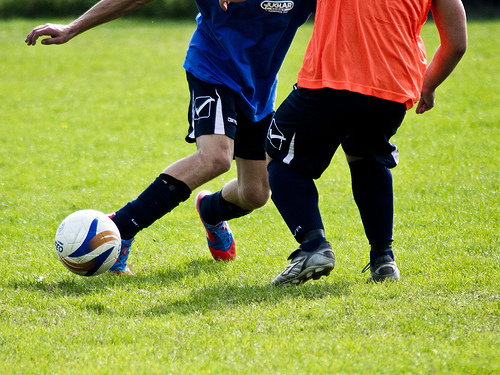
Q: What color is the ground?
A: Green.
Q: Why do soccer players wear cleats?
A: For traction.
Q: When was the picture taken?
A: Daytime.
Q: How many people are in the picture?
A: Two.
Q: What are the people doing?
A: Playing soccer.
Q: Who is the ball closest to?
A: The man with the blue shirt.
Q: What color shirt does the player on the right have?
A: Orange.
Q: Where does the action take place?
A: On a grassy field.